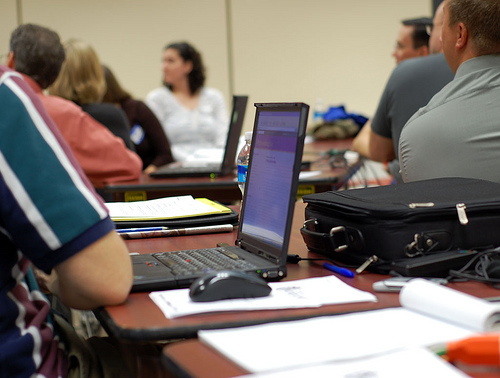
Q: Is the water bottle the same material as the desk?
A: No, the water bottle is made of plastic and the desk is made of wood.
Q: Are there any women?
A: Yes, there is a woman.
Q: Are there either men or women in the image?
A: Yes, there is a woman.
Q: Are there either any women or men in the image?
A: Yes, there is a woman.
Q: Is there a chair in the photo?
A: No, there are no chairs.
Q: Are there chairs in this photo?
A: No, there are no chairs.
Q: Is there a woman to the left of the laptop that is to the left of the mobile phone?
A: Yes, there is a woman to the left of the laptop computer.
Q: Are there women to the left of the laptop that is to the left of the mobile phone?
A: Yes, there is a woman to the left of the laptop computer.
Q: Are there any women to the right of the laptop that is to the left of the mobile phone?
A: No, the woman is to the left of the laptop computer.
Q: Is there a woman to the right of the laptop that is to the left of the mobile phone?
A: No, the woman is to the left of the laptop computer.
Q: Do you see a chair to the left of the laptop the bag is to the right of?
A: No, there is a woman to the left of the laptop.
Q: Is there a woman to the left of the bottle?
A: Yes, there is a woman to the left of the bottle.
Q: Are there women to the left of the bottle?
A: Yes, there is a woman to the left of the bottle.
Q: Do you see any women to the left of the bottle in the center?
A: Yes, there is a woman to the left of the bottle.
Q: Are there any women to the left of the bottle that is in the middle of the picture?
A: Yes, there is a woman to the left of the bottle.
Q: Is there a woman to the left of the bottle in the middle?
A: Yes, there is a woman to the left of the bottle.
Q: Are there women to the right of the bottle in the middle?
A: No, the woman is to the left of the bottle.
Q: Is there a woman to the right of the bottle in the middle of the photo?
A: No, the woman is to the left of the bottle.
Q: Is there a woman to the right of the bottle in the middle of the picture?
A: No, the woman is to the left of the bottle.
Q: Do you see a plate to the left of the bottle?
A: No, there is a woman to the left of the bottle.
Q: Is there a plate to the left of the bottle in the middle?
A: No, there is a woman to the left of the bottle.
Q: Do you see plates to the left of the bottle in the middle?
A: No, there is a woman to the left of the bottle.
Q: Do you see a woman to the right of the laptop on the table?
A: No, the woman is to the left of the laptop.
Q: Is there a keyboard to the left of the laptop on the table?
A: No, there is a woman to the left of the laptop computer.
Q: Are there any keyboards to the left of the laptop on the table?
A: No, there is a woman to the left of the laptop computer.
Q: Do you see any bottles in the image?
A: Yes, there is a bottle.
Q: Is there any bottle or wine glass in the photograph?
A: Yes, there is a bottle.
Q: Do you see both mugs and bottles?
A: No, there is a bottle but no mugs.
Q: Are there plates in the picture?
A: No, there are no plates.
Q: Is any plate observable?
A: No, there are no plates.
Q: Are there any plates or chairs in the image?
A: No, there are no plates or chairs.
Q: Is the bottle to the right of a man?
A: Yes, the bottle is to the right of a man.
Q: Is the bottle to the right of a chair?
A: No, the bottle is to the right of a man.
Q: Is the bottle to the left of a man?
A: No, the bottle is to the right of a man.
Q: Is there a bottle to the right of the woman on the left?
A: Yes, there is a bottle to the right of the woman.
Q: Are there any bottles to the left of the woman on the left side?
A: No, the bottle is to the right of the woman.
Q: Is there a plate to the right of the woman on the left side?
A: No, there is a bottle to the right of the woman.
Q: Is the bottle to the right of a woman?
A: Yes, the bottle is to the right of a woman.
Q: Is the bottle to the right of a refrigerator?
A: No, the bottle is to the right of a woman.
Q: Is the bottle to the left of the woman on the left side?
A: No, the bottle is to the right of the woman.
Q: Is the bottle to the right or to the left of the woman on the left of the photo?
A: The bottle is to the right of the woman.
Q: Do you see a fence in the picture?
A: No, there are no fences.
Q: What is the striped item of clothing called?
A: The clothing item is a shirt.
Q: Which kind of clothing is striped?
A: The clothing is a shirt.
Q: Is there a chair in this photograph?
A: No, there are no chairs.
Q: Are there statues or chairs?
A: No, there are no chairs or statues.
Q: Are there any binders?
A: No, there are no binders.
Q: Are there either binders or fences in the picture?
A: No, there are no binders or fences.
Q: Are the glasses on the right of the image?
A: Yes, the glasses are on the right of the image.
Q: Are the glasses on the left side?
A: No, the glasses are on the right of the image.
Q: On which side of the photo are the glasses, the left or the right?
A: The glasses are on the right of the image.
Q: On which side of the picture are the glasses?
A: The glasses are on the right of the image.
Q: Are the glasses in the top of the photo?
A: Yes, the glasses are in the top of the image.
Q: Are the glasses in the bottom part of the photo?
A: No, the glasses are in the top of the image.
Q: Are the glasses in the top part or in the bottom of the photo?
A: The glasses are in the top of the image.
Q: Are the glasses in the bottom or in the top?
A: The glasses are in the top of the image.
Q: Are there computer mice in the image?
A: Yes, there is a computer mouse.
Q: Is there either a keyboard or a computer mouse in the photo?
A: Yes, there is a computer mouse.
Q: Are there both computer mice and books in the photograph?
A: No, there is a computer mouse but no books.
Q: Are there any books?
A: No, there are no books.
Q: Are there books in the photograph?
A: No, there are no books.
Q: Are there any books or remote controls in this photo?
A: No, there are no books or remote controls.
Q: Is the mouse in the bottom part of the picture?
A: Yes, the mouse is in the bottom of the image.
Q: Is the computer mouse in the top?
A: No, the computer mouse is in the bottom of the image.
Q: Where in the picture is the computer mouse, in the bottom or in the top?
A: The computer mouse is in the bottom of the image.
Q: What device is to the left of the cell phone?
A: The device is a computer mouse.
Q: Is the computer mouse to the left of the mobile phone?
A: Yes, the computer mouse is to the left of the mobile phone.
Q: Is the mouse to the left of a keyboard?
A: No, the mouse is to the left of the mobile phone.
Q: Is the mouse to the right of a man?
A: Yes, the mouse is to the right of a man.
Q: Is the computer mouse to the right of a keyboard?
A: No, the computer mouse is to the right of a man.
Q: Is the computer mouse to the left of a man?
A: No, the computer mouse is to the right of a man.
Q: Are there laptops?
A: Yes, there is a laptop.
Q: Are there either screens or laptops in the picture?
A: Yes, there is a laptop.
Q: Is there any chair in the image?
A: No, there are no chairs.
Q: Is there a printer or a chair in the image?
A: No, there are no chairs or printers.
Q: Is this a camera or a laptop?
A: This is a laptop.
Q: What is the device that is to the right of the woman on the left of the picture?
A: The device is a laptop.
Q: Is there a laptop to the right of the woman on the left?
A: Yes, there is a laptop to the right of the woman.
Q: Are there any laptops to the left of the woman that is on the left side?
A: No, the laptop is to the right of the woman.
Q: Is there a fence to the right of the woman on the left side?
A: No, there is a laptop to the right of the woman.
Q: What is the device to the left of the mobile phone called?
A: The device is a laptop.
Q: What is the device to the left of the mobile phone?
A: The device is a laptop.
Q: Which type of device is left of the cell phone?
A: The device is a laptop.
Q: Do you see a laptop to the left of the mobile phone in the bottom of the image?
A: Yes, there is a laptop to the left of the mobile phone.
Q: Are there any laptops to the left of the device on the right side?
A: Yes, there is a laptop to the left of the mobile phone.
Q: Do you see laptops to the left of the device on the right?
A: Yes, there is a laptop to the left of the mobile phone.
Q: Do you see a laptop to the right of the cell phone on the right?
A: No, the laptop is to the left of the cellphone.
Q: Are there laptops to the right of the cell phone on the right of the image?
A: No, the laptop is to the left of the cellphone.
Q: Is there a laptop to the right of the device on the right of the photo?
A: No, the laptop is to the left of the cellphone.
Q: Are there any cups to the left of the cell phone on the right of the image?
A: No, there is a laptop to the left of the mobile phone.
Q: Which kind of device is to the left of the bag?
A: The device is a laptop.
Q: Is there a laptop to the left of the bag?
A: Yes, there is a laptop to the left of the bag.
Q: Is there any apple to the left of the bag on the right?
A: No, there is a laptop to the left of the bag.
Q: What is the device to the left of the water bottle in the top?
A: The device is a laptop.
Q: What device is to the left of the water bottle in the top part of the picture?
A: The device is a laptop.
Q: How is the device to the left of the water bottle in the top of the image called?
A: The device is a laptop.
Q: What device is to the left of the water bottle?
A: The device is a laptop.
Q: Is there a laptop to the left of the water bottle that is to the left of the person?
A: Yes, there is a laptop to the left of the water bottle.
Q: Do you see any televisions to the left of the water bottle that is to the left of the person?
A: No, there is a laptop to the left of the water bottle.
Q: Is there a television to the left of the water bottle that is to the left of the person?
A: No, there is a laptop to the left of the water bottle.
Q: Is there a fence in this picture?
A: No, there are no fences.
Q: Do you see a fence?
A: No, there are no fences.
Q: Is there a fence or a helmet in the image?
A: No, there are no fences or helmets.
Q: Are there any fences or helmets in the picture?
A: No, there are no fences or helmets.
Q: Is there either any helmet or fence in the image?
A: No, there are no fences or helmets.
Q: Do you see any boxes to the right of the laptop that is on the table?
A: No, there is a man to the right of the laptop.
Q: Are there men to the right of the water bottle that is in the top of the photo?
A: Yes, there is a man to the right of the water bottle.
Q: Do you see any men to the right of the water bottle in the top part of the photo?
A: Yes, there is a man to the right of the water bottle.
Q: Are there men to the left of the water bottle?
A: No, the man is to the right of the water bottle.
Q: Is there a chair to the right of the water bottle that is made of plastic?
A: No, there is a man to the right of the water bottle.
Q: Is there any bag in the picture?
A: Yes, there is a bag.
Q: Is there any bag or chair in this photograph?
A: Yes, there is a bag.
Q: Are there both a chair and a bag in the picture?
A: No, there is a bag but no chairs.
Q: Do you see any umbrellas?
A: No, there are no umbrellas.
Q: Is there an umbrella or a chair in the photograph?
A: No, there are no umbrellas or chairs.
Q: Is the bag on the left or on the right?
A: The bag is on the right of the image.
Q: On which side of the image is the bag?
A: The bag is on the right of the image.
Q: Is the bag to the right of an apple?
A: No, the bag is to the right of a laptop.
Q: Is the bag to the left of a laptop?
A: No, the bag is to the right of a laptop.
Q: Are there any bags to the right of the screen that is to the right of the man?
A: Yes, there is a bag to the right of the screen.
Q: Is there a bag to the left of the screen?
A: No, the bag is to the right of the screen.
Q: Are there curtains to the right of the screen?
A: No, there is a bag to the right of the screen.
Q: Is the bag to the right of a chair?
A: No, the bag is to the right of the screen.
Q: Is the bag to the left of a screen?
A: No, the bag is to the right of a screen.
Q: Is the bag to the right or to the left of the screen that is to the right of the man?
A: The bag is to the right of the screen.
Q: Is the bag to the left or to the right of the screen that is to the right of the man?
A: The bag is to the right of the screen.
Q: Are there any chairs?
A: No, there are no chairs.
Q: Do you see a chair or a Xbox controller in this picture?
A: No, there are no chairs or Xbox controllers.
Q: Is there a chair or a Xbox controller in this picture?
A: No, there are no chairs or Xbox controllers.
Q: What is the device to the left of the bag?
A: The device is a screen.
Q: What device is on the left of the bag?
A: The device is a screen.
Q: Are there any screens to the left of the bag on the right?
A: Yes, there is a screen to the left of the bag.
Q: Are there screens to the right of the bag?
A: No, the screen is to the left of the bag.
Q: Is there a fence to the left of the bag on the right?
A: No, there is a screen to the left of the bag.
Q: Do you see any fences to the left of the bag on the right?
A: No, there is a screen to the left of the bag.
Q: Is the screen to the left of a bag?
A: Yes, the screen is to the left of a bag.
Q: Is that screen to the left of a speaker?
A: No, the screen is to the left of a bag.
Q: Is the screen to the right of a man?
A: Yes, the screen is to the right of a man.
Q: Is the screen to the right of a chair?
A: No, the screen is to the right of a man.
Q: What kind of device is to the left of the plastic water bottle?
A: The device is a screen.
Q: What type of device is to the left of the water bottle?
A: The device is a screen.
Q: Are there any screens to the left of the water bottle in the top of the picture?
A: Yes, there is a screen to the left of the water bottle.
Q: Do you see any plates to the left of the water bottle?
A: No, there is a screen to the left of the water bottle.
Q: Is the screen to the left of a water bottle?
A: Yes, the screen is to the left of a water bottle.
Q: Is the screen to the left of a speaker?
A: No, the screen is to the left of a water bottle.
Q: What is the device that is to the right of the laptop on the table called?
A: The device is a screen.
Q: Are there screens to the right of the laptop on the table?
A: Yes, there is a screen to the right of the laptop.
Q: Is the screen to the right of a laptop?
A: Yes, the screen is to the right of a laptop.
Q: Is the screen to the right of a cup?
A: No, the screen is to the right of a laptop.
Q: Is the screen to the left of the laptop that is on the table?
A: No, the screen is to the right of the laptop computer.